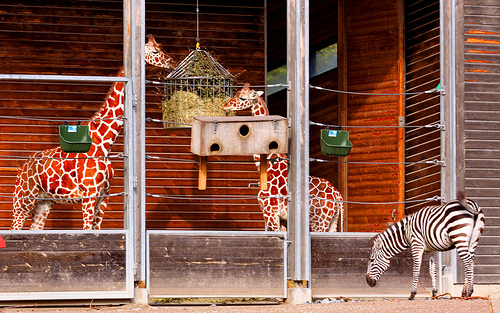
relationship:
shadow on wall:
[143, 186, 243, 237] [0, 0, 290, 236]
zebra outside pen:
[354, 195, 480, 291] [61, 19, 417, 270]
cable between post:
[306, 72, 457, 118] [295, 23, 321, 279]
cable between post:
[306, 72, 457, 118] [434, 13, 474, 231]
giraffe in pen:
[22, 16, 153, 268] [28, 7, 378, 252]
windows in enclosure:
[222, 34, 402, 93] [6, 3, 496, 295]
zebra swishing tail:
[364, 191, 487, 245] [452, 180, 488, 230]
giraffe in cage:
[190, 49, 352, 256] [21, 8, 438, 268]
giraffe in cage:
[10, 32, 180, 230] [21, 8, 438, 268]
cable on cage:
[295, 73, 451, 129] [2, 20, 442, 223]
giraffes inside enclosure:
[32, 6, 347, 233] [6, 3, 484, 267]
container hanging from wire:
[51, 107, 92, 167] [32, 119, 126, 126]